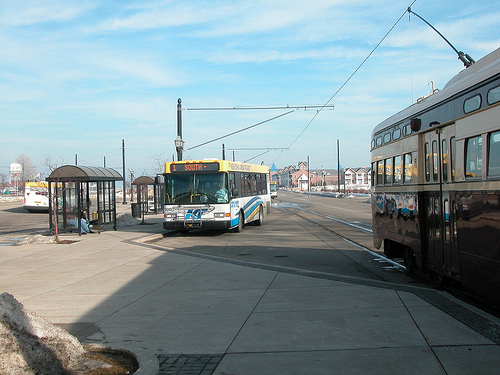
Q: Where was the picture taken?
A: It was taken at the city.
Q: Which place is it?
A: It is a city.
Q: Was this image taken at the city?
A: Yes, it was taken in the city.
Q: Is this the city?
A: Yes, it is the city.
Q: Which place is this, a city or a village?
A: It is a city.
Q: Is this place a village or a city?
A: It is a city.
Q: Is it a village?
A: No, it is a city.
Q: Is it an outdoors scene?
A: Yes, it is outdoors.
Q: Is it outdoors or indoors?
A: It is outdoors.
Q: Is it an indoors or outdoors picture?
A: It is outdoors.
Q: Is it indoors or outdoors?
A: It is outdoors.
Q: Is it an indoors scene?
A: No, it is outdoors.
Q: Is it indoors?
A: No, it is outdoors.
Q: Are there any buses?
A: Yes, there is a bus.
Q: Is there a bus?
A: Yes, there is a bus.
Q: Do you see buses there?
A: Yes, there is a bus.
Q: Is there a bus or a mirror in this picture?
A: Yes, there is a bus.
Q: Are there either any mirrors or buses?
A: Yes, there is a bus.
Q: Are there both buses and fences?
A: No, there is a bus but no fences.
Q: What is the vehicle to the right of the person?
A: The vehicle is a bus.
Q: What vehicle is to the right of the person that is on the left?
A: The vehicle is a bus.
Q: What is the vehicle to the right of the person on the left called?
A: The vehicle is a bus.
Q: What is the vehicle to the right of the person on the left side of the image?
A: The vehicle is a bus.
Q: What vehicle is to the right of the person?
A: The vehicle is a bus.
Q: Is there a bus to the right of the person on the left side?
A: Yes, there is a bus to the right of the person.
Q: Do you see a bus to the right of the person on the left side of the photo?
A: Yes, there is a bus to the right of the person.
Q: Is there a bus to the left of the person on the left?
A: No, the bus is to the right of the person.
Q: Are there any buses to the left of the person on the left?
A: No, the bus is to the right of the person.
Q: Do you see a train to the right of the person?
A: No, there is a bus to the right of the person.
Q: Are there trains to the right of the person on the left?
A: No, there is a bus to the right of the person.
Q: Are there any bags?
A: No, there are no bags.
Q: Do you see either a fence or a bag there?
A: No, there are no bags or fences.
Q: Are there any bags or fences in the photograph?
A: No, there are no bags or fences.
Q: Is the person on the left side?
A: Yes, the person is on the left of the image.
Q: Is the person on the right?
A: No, the person is on the left of the image.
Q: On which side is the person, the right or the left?
A: The person is on the left of the image.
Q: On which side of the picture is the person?
A: The person is on the left of the image.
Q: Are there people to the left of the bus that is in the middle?
A: Yes, there is a person to the left of the bus.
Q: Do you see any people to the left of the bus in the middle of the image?
A: Yes, there is a person to the left of the bus.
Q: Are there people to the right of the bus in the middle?
A: No, the person is to the left of the bus.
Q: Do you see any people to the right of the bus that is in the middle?
A: No, the person is to the left of the bus.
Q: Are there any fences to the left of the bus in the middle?
A: No, there is a person to the left of the bus.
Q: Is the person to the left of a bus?
A: Yes, the person is to the left of a bus.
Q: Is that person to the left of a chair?
A: No, the person is to the left of a bus.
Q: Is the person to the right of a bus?
A: No, the person is to the left of a bus.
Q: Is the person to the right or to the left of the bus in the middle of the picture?
A: The person is to the left of the bus.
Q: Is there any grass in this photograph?
A: Yes, there is grass.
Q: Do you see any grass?
A: Yes, there is grass.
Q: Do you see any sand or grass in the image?
A: Yes, there is grass.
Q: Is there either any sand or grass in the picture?
A: Yes, there is grass.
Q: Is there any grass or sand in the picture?
A: Yes, there is grass.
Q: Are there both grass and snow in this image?
A: Yes, there are both grass and snow.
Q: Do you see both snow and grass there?
A: Yes, there are both grass and snow.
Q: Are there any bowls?
A: No, there are no bowls.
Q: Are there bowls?
A: No, there are no bowls.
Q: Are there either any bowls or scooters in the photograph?
A: No, there are no bowls or scooters.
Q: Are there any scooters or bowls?
A: No, there are no bowls or scooters.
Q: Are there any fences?
A: No, there are no fences.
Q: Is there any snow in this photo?
A: Yes, there is snow.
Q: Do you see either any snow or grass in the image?
A: Yes, there is snow.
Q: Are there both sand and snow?
A: No, there is snow but no sand.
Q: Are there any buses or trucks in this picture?
A: Yes, there is a bus.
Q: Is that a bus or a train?
A: That is a bus.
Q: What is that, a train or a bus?
A: That is a bus.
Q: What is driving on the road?
A: The bus is driving on the road.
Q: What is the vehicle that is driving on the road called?
A: The vehicle is a bus.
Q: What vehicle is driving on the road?
A: The vehicle is a bus.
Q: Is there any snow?
A: Yes, there is snow.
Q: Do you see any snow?
A: Yes, there is snow.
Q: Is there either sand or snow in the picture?
A: Yes, there is snow.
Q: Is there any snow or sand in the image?
A: Yes, there is snow.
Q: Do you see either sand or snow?
A: Yes, there is snow.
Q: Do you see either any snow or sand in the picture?
A: Yes, there is snow.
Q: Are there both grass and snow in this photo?
A: Yes, there are both snow and grass.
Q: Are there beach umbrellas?
A: No, there are no beach umbrellas.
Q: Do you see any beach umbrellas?
A: No, there are no beach umbrellas.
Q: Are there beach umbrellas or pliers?
A: No, there are no beach umbrellas or pliers.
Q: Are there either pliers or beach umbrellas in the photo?
A: No, there are no beach umbrellas or pliers.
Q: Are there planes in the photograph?
A: No, there are no planes.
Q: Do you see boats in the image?
A: No, there are no boats.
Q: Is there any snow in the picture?
A: Yes, there is snow.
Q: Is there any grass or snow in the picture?
A: Yes, there is snow.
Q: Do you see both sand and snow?
A: No, there is snow but no sand.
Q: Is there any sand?
A: No, there is no sand.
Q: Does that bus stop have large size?
A: Yes, the bus stop is large.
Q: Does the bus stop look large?
A: Yes, the bus stop is large.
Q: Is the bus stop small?
A: No, the bus stop is large.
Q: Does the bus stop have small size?
A: No, the bus stop is large.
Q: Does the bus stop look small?
A: No, the bus stop is large.